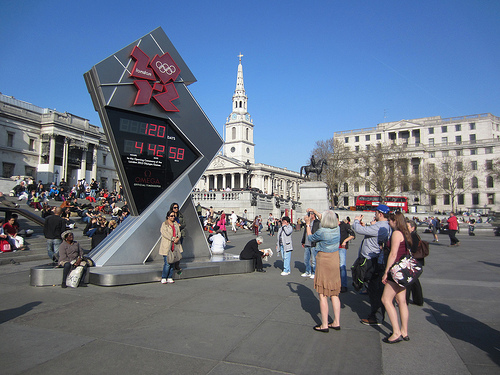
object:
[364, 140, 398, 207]
trees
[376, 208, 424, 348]
woman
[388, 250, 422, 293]
bag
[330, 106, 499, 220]
building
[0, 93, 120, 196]
building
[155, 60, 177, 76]
olympic symbol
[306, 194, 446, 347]
people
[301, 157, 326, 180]
statue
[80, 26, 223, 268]
statue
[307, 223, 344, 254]
blue jacket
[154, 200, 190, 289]
ladies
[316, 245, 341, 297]
dress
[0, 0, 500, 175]
sky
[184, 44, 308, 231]
building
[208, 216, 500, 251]
back ground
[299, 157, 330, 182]
horse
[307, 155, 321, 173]
rider